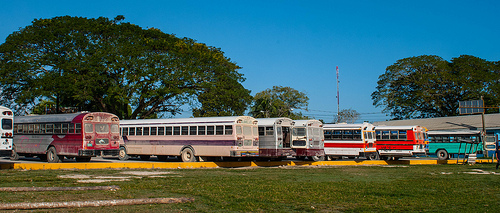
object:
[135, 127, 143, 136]
window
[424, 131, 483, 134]
top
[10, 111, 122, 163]
school bus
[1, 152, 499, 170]
parking lot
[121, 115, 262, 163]
bus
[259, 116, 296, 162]
school bus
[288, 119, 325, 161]
school bus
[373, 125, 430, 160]
school bus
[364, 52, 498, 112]
tree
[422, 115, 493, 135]
building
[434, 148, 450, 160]
tire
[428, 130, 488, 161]
bus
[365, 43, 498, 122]
tree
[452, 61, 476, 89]
leaves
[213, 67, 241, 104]
leaves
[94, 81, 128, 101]
leaves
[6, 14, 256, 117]
tree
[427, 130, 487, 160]
one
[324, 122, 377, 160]
bus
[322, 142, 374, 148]
stripe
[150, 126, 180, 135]
window